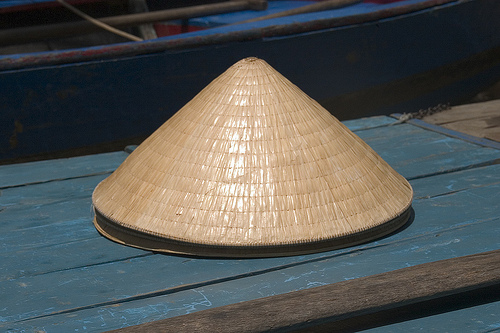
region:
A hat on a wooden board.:
[81, 58, 412, 253]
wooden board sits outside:
[1, 112, 490, 332]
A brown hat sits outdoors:
[90, 53, 417, 255]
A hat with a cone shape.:
[88, 55, 417, 252]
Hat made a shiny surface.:
[91, 52, 420, 263]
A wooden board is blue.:
[1, 52, 491, 331]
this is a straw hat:
[8, 28, 442, 326]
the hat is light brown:
[168, 58, 326, 206]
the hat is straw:
[148, 48, 400, 250]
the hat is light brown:
[187, 103, 389, 313]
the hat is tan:
[181, 127, 335, 251]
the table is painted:
[10, 221, 122, 303]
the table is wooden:
[41, 241, 129, 315]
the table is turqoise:
[10, 231, 130, 325]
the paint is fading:
[54, 225, 174, 287]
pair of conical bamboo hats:
[86, 50, 418, 265]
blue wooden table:
[3, 110, 498, 325]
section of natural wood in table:
[411, 98, 499, 149]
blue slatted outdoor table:
[8, 106, 498, 320]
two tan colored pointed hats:
[83, 54, 416, 259]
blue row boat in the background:
[17, 0, 486, 153]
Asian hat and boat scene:
[6, 6, 496, 325]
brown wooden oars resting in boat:
[56, 4, 269, 40]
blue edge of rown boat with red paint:
[2, 6, 414, 76]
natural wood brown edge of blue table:
[153, 247, 498, 327]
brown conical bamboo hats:
[86, 50, 418, 265]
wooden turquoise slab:
[7, 103, 499, 325]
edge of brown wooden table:
[405, 98, 499, 147]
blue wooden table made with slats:
[1, 105, 494, 316]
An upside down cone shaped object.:
[86, 46, 422, 260]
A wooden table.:
[1, 99, 498, 330]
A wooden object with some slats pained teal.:
[1, 99, 497, 331]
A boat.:
[4, 0, 497, 167]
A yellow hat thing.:
[97, 36, 431, 238]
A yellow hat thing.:
[84, 201, 423, 244]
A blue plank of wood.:
[3, 247, 301, 295]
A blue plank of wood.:
[8, 150, 131, 188]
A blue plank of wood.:
[123, 143, 139, 151]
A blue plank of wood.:
[355, 112, 499, 185]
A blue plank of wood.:
[18, 110, 496, 330]